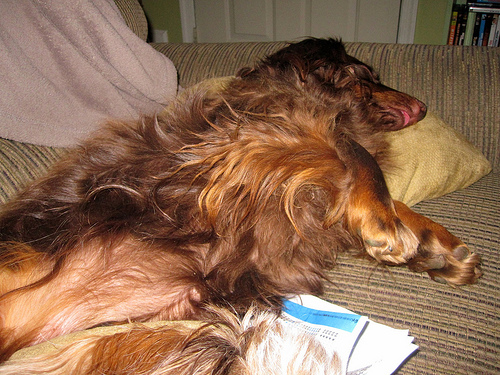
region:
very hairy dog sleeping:
[193, 28, 480, 315]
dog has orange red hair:
[148, 113, 359, 235]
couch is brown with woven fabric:
[334, 35, 479, 367]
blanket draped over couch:
[25, 6, 185, 191]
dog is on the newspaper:
[281, 291, 365, 369]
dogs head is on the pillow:
[332, 47, 463, 205]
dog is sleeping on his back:
[23, 32, 490, 286]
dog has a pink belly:
[78, 242, 222, 366]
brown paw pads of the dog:
[421, 238, 476, 307]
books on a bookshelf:
[438, 4, 499, 54]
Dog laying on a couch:
[8, 38, 471, 372]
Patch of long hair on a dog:
[54, 133, 111, 200]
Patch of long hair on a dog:
[15, 171, 57, 228]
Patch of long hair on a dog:
[48, 214, 123, 264]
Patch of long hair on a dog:
[85, 161, 210, 269]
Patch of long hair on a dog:
[101, 86, 202, 184]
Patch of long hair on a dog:
[174, 59, 272, 159]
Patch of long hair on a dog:
[253, 51, 336, 137]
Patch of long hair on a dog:
[258, 154, 354, 243]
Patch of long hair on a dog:
[175, 195, 295, 277]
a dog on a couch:
[2, 26, 470, 373]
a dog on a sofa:
[5, 12, 497, 367]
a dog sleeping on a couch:
[2, 26, 496, 373]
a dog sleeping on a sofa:
[1, 16, 478, 373]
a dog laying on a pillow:
[168, 40, 496, 230]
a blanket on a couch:
[4, 2, 175, 163]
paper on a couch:
[228, 285, 409, 373]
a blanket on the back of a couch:
[0, 2, 218, 162]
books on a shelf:
[441, 2, 498, 54]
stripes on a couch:
[364, 268, 498, 342]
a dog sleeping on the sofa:
[0, 32, 485, 370]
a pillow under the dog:
[164, 75, 489, 208]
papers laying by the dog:
[241, 294, 418, 374]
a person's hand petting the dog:
[0, 220, 202, 353]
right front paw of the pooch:
[339, 133, 418, 263]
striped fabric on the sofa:
[312, 251, 498, 373]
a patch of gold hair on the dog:
[184, 128, 351, 230]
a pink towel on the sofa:
[0, 0, 177, 150]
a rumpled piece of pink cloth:
[1, 0, 172, 149]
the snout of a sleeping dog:
[370, 81, 427, 128]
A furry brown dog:
[0, 40, 480, 372]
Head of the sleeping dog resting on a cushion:
[310, 39, 425, 129]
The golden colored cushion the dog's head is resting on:
[366, 109, 491, 204]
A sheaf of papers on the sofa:
[243, 296, 419, 373]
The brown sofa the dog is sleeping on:
[2, 45, 499, 372]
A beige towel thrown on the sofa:
[0, 1, 177, 145]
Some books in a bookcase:
[446, 0, 498, 43]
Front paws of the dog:
[365, 225, 483, 287]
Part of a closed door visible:
[176, 0, 416, 42]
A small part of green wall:
[138, 0, 449, 41]